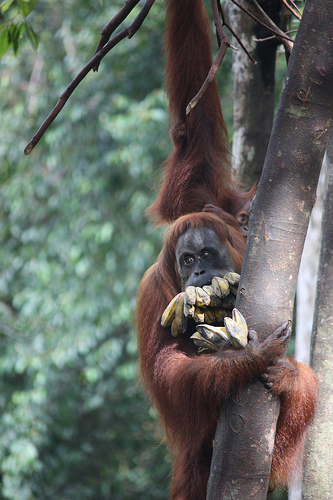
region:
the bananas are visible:
[156, 259, 327, 404]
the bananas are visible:
[157, 265, 244, 392]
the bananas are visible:
[181, 252, 263, 447]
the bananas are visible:
[143, 213, 214, 341]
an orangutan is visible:
[147, 264, 238, 445]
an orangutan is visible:
[193, 342, 244, 452]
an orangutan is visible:
[147, 333, 213, 484]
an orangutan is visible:
[118, 300, 196, 442]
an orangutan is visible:
[169, 313, 280, 484]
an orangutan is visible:
[147, 332, 237, 415]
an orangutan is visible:
[80, 251, 280, 402]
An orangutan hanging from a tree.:
[136, 0, 319, 499]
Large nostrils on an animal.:
[191, 268, 206, 276]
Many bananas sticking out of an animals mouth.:
[159, 269, 240, 336]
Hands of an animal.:
[249, 318, 295, 396]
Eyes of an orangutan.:
[185, 248, 212, 263]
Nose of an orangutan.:
[193, 262, 206, 276]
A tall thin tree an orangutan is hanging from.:
[204, 1, 331, 497]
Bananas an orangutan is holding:
[189, 308, 249, 352]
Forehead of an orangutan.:
[173, 229, 215, 249]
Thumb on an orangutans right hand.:
[248, 328, 257, 345]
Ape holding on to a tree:
[123, 208, 319, 486]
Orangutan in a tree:
[132, 204, 329, 491]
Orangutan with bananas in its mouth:
[128, 209, 319, 492]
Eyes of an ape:
[168, 242, 221, 268]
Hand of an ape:
[243, 308, 299, 360]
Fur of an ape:
[152, 348, 209, 444]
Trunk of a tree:
[240, 185, 298, 313]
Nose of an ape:
[190, 264, 205, 275]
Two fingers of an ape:
[271, 318, 292, 346]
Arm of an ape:
[154, 25, 235, 181]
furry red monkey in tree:
[99, 27, 310, 492]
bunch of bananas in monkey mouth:
[164, 277, 254, 316]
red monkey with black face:
[155, 204, 265, 335]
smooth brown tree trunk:
[234, 155, 310, 491]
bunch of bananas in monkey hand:
[188, 316, 267, 356]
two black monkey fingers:
[263, 313, 297, 346]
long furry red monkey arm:
[121, 0, 251, 222]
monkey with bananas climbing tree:
[137, 155, 302, 488]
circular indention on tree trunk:
[224, 409, 247, 434]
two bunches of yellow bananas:
[153, 268, 270, 349]